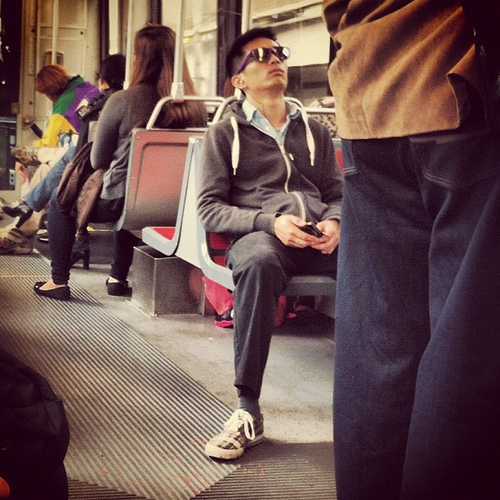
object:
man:
[195, 26, 347, 459]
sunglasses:
[239, 45, 285, 76]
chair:
[189, 135, 340, 298]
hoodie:
[198, 96, 347, 233]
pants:
[225, 217, 341, 398]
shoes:
[200, 409, 266, 457]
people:
[33, 26, 212, 300]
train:
[0, 0, 500, 498]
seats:
[89, 125, 186, 234]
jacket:
[321, 2, 500, 142]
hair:
[129, 23, 210, 128]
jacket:
[76, 91, 111, 150]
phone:
[301, 222, 325, 240]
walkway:
[0, 228, 250, 499]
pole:
[169, 1, 188, 97]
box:
[129, 247, 200, 319]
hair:
[222, 26, 283, 74]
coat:
[34, 72, 103, 147]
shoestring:
[228, 114, 243, 176]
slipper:
[33, 281, 76, 299]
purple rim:
[237, 48, 250, 73]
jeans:
[23, 148, 76, 211]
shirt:
[89, 92, 210, 197]